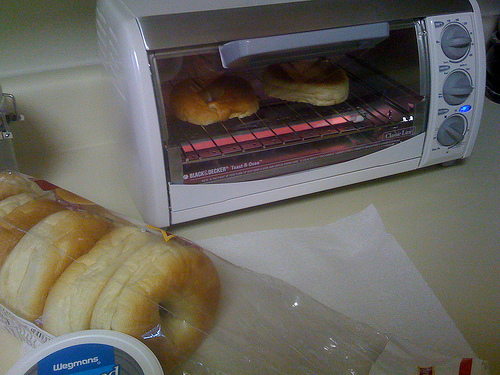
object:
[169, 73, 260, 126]
bagel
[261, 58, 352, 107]
bagel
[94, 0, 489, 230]
toaster oven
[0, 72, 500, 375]
counter top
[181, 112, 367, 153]
light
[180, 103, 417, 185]
coil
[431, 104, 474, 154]
timer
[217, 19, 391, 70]
handle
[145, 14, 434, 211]
door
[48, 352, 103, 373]
wegmans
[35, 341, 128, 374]
label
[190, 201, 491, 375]
paper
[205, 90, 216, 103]
hole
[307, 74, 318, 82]
hole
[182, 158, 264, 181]
label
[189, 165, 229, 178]
black and decker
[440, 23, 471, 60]
knob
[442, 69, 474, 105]
knob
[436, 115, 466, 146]
knob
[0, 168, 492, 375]
bag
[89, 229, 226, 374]
bagel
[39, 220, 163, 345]
bagel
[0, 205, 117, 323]
bagel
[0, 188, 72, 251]
bagel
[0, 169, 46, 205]
bagel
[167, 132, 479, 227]
bottom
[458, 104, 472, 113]
light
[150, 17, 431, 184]
rack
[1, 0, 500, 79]
backsplash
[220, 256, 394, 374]
space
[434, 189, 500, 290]
part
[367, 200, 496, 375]
edge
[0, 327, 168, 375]
container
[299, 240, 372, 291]
part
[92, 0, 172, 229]
edge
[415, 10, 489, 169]
part